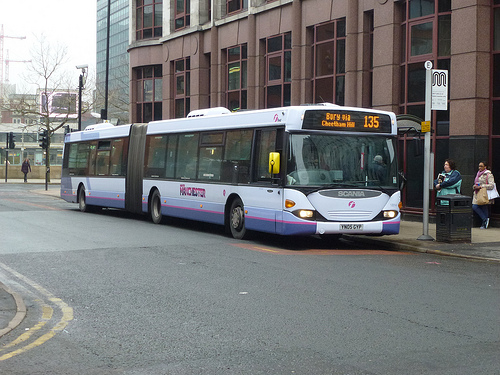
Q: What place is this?
A: It is a city.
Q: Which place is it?
A: It is a city.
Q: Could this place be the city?
A: Yes, it is the city.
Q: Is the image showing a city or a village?
A: It is showing a city.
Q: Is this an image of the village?
A: No, the picture is showing the city.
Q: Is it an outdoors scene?
A: Yes, it is outdoors.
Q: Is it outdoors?
A: Yes, it is outdoors.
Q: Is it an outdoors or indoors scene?
A: It is outdoors.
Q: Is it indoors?
A: No, it is outdoors.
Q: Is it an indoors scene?
A: No, it is outdoors.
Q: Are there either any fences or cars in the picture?
A: No, there are no cars or fences.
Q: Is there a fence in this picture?
A: No, there are no fences.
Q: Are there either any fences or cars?
A: No, there are no fences or cars.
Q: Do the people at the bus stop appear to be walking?
A: Yes, the people are walking.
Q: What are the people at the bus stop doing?
A: The people are walking.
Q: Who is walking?
A: The people are walking.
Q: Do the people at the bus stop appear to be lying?
A: No, the people are walking.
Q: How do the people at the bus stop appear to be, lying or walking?
A: The people are walking.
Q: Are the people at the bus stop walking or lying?
A: The people are walking.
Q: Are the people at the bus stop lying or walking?
A: The people are walking.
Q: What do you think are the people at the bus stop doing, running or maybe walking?
A: The people are walking.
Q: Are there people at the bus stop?
A: Yes, there are people at the bus stop.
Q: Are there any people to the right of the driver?
A: Yes, there are people to the right of the driver.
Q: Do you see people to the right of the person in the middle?
A: Yes, there are people to the right of the driver.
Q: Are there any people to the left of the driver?
A: No, the people are to the right of the driver.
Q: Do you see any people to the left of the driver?
A: No, the people are to the right of the driver.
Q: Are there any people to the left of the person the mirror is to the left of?
A: No, the people are to the right of the driver.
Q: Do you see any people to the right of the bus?
A: Yes, there are people to the right of the bus.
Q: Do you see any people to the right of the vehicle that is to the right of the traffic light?
A: Yes, there are people to the right of the bus.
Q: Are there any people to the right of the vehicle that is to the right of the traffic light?
A: Yes, there are people to the right of the bus.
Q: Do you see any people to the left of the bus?
A: No, the people are to the right of the bus.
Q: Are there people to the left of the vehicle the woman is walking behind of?
A: No, the people are to the right of the bus.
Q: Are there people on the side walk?
A: Yes, there are people on the side walk.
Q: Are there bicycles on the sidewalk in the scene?
A: No, there are people on the sidewalk.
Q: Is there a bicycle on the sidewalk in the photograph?
A: No, there are people on the sidewalk.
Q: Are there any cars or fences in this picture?
A: No, there are no fences or cars.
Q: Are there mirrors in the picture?
A: Yes, there is a mirror.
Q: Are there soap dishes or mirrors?
A: Yes, there is a mirror.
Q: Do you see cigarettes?
A: No, there are no cigarettes.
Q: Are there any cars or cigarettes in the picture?
A: No, there are no cigarettes or cars.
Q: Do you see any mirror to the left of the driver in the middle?
A: Yes, there is a mirror to the left of the driver.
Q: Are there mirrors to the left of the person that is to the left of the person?
A: Yes, there is a mirror to the left of the driver.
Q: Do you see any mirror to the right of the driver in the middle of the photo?
A: No, the mirror is to the left of the driver.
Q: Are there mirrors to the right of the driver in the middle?
A: No, the mirror is to the left of the driver.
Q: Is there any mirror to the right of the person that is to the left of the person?
A: No, the mirror is to the left of the driver.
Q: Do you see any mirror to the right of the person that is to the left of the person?
A: No, the mirror is to the left of the driver.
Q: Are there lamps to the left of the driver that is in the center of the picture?
A: No, there is a mirror to the left of the driver.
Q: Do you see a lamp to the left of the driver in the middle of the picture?
A: No, there is a mirror to the left of the driver.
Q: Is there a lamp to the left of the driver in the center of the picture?
A: No, there is a mirror to the left of the driver.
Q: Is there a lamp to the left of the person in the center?
A: No, there is a mirror to the left of the driver.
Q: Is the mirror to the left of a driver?
A: Yes, the mirror is to the left of a driver.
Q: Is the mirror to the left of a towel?
A: No, the mirror is to the left of a driver.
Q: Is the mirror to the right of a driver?
A: No, the mirror is to the left of a driver.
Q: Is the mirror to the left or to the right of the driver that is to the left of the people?
A: The mirror is to the left of the driver.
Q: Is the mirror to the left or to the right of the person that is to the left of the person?
A: The mirror is to the left of the driver.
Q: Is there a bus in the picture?
A: Yes, there is a bus.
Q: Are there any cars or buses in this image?
A: Yes, there is a bus.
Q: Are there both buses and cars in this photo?
A: No, there is a bus but no cars.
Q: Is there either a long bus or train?
A: Yes, there is a long bus.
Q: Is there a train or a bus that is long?
A: Yes, the bus is long.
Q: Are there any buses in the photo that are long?
A: Yes, there is a long bus.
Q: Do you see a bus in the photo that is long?
A: Yes, there is a bus that is long.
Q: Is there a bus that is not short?
A: Yes, there is a long bus.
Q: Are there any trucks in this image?
A: No, there are no trucks.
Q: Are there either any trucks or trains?
A: No, there are no trucks or trains.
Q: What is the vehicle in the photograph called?
A: The vehicle is a bus.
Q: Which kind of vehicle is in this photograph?
A: The vehicle is a bus.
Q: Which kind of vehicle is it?
A: The vehicle is a bus.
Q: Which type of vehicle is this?
A: This is a bus.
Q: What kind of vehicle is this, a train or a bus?
A: This is a bus.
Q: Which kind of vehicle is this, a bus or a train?
A: This is a bus.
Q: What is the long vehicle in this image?
A: The vehicle is a bus.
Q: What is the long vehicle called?
A: The vehicle is a bus.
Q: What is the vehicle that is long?
A: The vehicle is a bus.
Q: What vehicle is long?
A: The vehicle is a bus.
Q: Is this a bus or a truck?
A: This is a bus.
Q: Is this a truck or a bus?
A: This is a bus.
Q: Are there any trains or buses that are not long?
A: No, there is a bus but it is long.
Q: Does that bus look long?
A: Yes, the bus is long.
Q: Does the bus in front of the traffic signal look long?
A: Yes, the bus is long.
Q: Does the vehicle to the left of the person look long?
A: Yes, the bus is long.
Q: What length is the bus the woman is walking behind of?
A: The bus is long.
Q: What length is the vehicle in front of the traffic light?
A: The bus is long.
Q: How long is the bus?
A: The bus is long.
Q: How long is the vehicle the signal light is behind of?
A: The bus is long.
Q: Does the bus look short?
A: No, the bus is long.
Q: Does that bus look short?
A: No, the bus is long.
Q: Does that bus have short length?
A: No, the bus is long.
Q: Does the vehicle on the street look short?
A: No, the bus is long.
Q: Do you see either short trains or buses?
A: No, there is a bus but it is long.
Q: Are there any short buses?
A: No, there is a bus but it is long.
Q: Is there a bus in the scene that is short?
A: No, there is a bus but it is long.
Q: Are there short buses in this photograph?
A: No, there is a bus but it is long.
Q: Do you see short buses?
A: No, there is a bus but it is long.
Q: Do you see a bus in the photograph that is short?
A: No, there is a bus but it is long.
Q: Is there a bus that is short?
A: No, there is a bus but it is long.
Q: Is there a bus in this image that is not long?
A: No, there is a bus but it is long.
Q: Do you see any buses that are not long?
A: No, there is a bus but it is long.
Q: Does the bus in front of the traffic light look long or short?
A: The bus is long.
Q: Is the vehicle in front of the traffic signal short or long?
A: The bus is long.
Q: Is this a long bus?
A: Yes, this is a long bus.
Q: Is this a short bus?
A: No, this is a long bus.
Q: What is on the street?
A: The bus is on the street.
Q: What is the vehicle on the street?
A: The vehicle is a bus.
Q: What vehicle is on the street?
A: The vehicle is a bus.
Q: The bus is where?
A: The bus is on the street.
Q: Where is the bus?
A: The bus is on the street.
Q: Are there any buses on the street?
A: Yes, there is a bus on the street.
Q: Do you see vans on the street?
A: No, there is a bus on the street.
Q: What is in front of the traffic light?
A: The bus is in front of the traffic light.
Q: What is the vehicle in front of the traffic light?
A: The vehicle is a bus.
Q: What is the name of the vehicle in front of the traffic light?
A: The vehicle is a bus.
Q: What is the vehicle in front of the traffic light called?
A: The vehicle is a bus.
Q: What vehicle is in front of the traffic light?
A: The vehicle is a bus.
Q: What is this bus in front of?
A: The bus is in front of the traffic light.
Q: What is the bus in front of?
A: The bus is in front of the traffic light.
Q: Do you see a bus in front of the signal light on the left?
A: Yes, there is a bus in front of the traffic signal.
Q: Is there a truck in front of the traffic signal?
A: No, there is a bus in front of the traffic signal.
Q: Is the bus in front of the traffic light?
A: Yes, the bus is in front of the traffic light.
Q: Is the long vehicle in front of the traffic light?
A: Yes, the bus is in front of the traffic light.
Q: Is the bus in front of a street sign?
A: No, the bus is in front of the traffic light.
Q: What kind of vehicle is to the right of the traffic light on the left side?
A: The vehicle is a bus.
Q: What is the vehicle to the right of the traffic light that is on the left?
A: The vehicle is a bus.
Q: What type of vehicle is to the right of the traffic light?
A: The vehicle is a bus.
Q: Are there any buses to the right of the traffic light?
A: Yes, there is a bus to the right of the traffic light.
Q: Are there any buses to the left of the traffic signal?
A: No, the bus is to the right of the traffic signal.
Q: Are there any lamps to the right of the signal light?
A: No, there is a bus to the right of the signal light.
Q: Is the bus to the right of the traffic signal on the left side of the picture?
A: Yes, the bus is to the right of the traffic signal.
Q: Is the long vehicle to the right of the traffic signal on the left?
A: Yes, the bus is to the right of the traffic signal.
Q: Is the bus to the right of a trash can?
A: No, the bus is to the right of the traffic signal.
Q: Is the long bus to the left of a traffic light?
A: No, the bus is to the right of a traffic light.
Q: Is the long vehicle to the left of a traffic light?
A: No, the bus is to the right of a traffic light.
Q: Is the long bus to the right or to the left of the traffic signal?
A: The bus is to the right of the traffic signal.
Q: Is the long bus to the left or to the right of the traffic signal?
A: The bus is to the right of the traffic signal.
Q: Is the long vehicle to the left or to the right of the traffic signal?
A: The bus is to the right of the traffic signal.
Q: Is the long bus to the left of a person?
A: Yes, the bus is to the left of a person.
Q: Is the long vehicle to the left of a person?
A: Yes, the bus is to the left of a person.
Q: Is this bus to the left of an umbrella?
A: No, the bus is to the left of a person.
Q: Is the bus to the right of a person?
A: No, the bus is to the left of a person.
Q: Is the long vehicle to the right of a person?
A: No, the bus is to the left of a person.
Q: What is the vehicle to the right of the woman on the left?
A: The vehicle is a bus.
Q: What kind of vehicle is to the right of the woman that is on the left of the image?
A: The vehicle is a bus.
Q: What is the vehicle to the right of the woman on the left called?
A: The vehicle is a bus.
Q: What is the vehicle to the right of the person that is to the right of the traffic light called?
A: The vehicle is a bus.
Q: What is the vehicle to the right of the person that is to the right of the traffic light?
A: The vehicle is a bus.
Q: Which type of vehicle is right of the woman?
A: The vehicle is a bus.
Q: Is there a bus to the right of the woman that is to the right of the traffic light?
A: Yes, there is a bus to the right of the woman.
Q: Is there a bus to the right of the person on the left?
A: Yes, there is a bus to the right of the woman.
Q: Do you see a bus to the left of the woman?
A: No, the bus is to the right of the woman.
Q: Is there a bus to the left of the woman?
A: No, the bus is to the right of the woman.